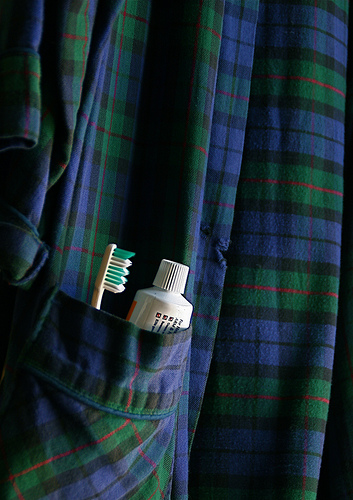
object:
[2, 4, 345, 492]
robe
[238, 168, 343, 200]
red line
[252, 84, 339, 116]
green line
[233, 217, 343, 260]
blue line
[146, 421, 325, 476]
blue lines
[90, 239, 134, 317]
toothbrush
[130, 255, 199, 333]
toothpaste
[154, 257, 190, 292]
cap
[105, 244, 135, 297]
bristles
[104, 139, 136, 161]
green section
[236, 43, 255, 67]
blue section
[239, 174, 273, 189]
red section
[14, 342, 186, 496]
plaid section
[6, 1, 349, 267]
plaid checkers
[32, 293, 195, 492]
pocket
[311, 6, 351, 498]
background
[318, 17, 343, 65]
blue block